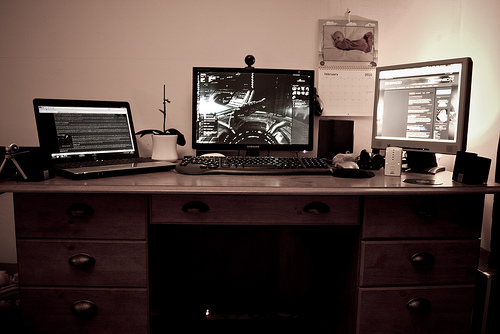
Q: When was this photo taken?
A: Yesterday.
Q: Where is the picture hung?
A: On the wall.